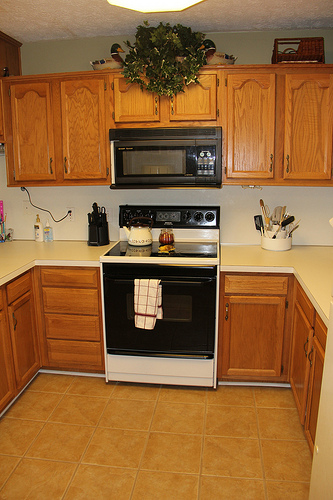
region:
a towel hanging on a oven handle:
[113, 278, 169, 340]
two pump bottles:
[26, 214, 51, 251]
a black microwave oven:
[94, 116, 229, 188]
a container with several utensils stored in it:
[243, 203, 307, 253]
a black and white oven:
[92, 206, 226, 386]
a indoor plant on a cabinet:
[90, 27, 228, 98]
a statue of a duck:
[92, 34, 129, 75]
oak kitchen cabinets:
[7, 67, 332, 194]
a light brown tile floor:
[44, 417, 237, 477]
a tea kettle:
[114, 214, 155, 251]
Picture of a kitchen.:
[13, 86, 331, 476]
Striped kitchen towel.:
[123, 269, 168, 336]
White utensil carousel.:
[248, 197, 307, 255]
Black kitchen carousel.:
[77, 198, 116, 249]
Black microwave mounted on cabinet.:
[101, 119, 229, 192]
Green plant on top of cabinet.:
[118, 18, 208, 98]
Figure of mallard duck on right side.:
[196, 30, 239, 67]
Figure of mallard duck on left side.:
[82, 36, 127, 72]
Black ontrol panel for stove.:
[117, 196, 223, 230]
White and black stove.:
[99, 195, 223, 394]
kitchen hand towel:
[126, 274, 174, 332]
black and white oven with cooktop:
[99, 197, 228, 395]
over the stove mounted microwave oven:
[102, 120, 229, 195]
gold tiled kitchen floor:
[19, 394, 291, 495]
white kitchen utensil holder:
[248, 197, 303, 251]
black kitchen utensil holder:
[77, 199, 111, 247]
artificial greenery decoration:
[122, 17, 208, 95]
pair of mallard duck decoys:
[87, 36, 239, 69]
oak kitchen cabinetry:
[6, 80, 106, 181]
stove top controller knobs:
[191, 209, 217, 224]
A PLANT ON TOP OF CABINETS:
[121, 16, 215, 102]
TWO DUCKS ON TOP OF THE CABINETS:
[83, 35, 243, 73]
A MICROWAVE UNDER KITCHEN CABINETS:
[101, 117, 237, 196]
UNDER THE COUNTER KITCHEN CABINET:
[218, 278, 296, 385]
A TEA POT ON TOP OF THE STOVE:
[116, 213, 156, 249]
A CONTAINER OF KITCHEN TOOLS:
[256, 195, 303, 254]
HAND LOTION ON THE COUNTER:
[20, 211, 64, 245]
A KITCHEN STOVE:
[95, 194, 227, 394]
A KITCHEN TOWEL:
[125, 275, 167, 337]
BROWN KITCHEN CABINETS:
[221, 58, 332, 194]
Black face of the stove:
[97, 263, 218, 358]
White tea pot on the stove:
[121, 214, 154, 248]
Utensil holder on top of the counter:
[251, 193, 302, 251]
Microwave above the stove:
[105, 121, 225, 194]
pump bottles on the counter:
[31, 208, 59, 243]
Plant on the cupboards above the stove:
[123, 16, 202, 95]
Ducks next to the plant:
[82, 40, 239, 68]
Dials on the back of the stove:
[122, 208, 215, 227]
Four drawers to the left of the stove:
[37, 263, 107, 377]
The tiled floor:
[1, 372, 312, 498]